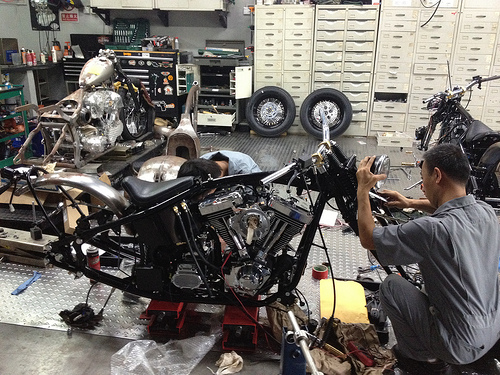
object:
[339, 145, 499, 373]
man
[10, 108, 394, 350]
motorcycle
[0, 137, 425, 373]
floor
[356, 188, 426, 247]
arm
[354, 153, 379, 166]
finger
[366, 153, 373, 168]
finger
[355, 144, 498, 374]
man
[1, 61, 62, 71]
shelf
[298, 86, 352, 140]
tire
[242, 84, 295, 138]
tire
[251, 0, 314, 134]
cabinet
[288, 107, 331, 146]
floor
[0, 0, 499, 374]
motorcycle shop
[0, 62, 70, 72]
counter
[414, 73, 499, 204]
motorcycle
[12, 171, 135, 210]
fender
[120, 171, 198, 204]
seat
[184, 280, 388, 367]
floor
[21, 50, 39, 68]
bottles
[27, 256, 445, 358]
floor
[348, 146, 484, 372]
man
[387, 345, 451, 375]
shoes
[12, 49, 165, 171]
motorcycle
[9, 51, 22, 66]
can